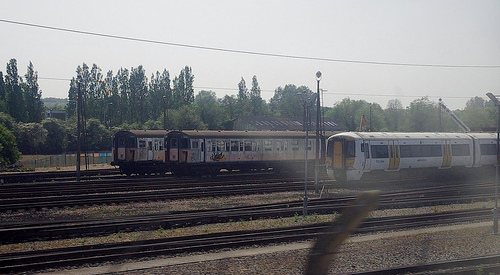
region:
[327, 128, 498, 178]
a white train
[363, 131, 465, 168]
a train with yellow doors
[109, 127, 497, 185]
three trains on rail trucks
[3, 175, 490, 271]
several rail trucks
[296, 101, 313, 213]
a grey light pole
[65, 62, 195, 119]
tall green trees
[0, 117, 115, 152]
a thick green bush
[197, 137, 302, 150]
windows of a train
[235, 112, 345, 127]
a building in the distance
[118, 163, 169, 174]
wheels of a train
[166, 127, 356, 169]
long multi- window train with graffiti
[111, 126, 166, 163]
long multi- window train with graffiti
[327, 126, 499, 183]
white yellow and black train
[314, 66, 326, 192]
tall pole with light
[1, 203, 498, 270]
long set of metal train tracks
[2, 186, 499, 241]
long set of metal train tracks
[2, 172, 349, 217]
long set of metal train tracks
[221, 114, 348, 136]
building with brown roof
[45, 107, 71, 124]
piece of building in the distance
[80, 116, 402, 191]
three trains are seen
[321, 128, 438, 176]
train is white and yellow in color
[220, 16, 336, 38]
sky is white in color.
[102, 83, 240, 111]
trees are green in color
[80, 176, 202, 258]
tracks are brown in color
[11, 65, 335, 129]
trees are seen behind the fence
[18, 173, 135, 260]
tracks are running parallel to each other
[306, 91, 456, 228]
sunlight reflection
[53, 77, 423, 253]
daytime picture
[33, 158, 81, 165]
compound wall is grey in color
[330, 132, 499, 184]
the train is white in color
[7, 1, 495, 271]
the scene is outdoors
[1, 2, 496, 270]
the photo was taken during daytime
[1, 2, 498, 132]
the sky is overcast and grey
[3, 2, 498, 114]
cables are hanging in the air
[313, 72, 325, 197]
a post is placed along the tracks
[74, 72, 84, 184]
a post is in place by trains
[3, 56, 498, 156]
the trees are lined along the tracks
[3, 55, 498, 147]
the trees are full of green leaves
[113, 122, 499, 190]
three trains are in the tracks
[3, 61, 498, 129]
Long row of trees beside train tracks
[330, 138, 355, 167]
Yellow door on train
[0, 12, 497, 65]
Electric wire hanging in sky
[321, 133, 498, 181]
White and yellow passenger train car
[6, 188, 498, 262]
Train tracks beside train car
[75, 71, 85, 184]
Dark brown pole beside train tracks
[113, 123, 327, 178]
Two silver train cars near farthest train tracks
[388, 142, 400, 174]
Yellow side door on train car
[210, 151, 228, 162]
Black graffiti on side of train car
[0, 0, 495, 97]
Light gray sky above train tracks